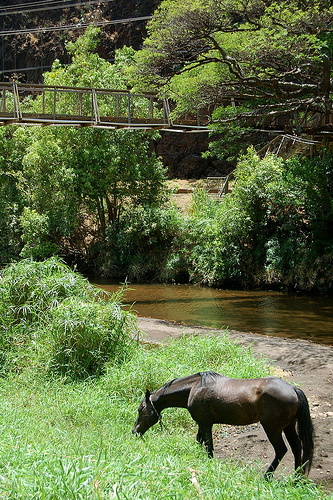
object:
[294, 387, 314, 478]
tail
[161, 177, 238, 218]
floor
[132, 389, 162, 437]
head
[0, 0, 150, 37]
electric wires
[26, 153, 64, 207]
plant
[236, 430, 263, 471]
rocks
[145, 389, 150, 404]
ear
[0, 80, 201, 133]
bridge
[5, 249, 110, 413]
bush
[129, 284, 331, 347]
river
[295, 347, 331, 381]
sand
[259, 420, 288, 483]
leg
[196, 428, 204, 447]
leg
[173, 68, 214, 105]
leaves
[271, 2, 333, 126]
trees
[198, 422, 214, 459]
leg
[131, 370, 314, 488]
horse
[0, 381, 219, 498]
grass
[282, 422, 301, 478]
leg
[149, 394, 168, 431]
strap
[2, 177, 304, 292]
terrain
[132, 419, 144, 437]
mouth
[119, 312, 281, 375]
ground area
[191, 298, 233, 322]
reflections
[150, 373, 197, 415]
neck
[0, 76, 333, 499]
nature area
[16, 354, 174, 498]
grass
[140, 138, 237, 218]
area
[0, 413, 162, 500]
ground